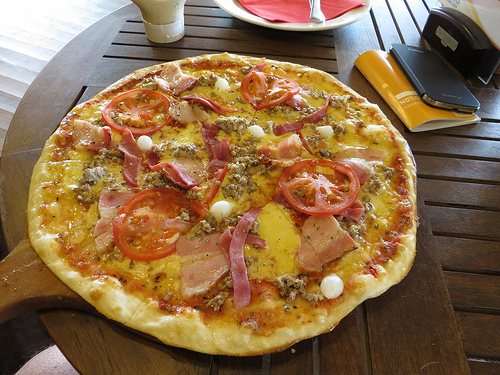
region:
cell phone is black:
[387, 33, 486, 113]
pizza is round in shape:
[21, 47, 423, 361]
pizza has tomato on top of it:
[23, 47, 425, 359]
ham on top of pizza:
[22, 47, 421, 357]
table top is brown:
[1, 0, 498, 371]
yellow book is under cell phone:
[350, 39, 482, 134]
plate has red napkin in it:
[211, 1, 373, 32]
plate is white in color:
[212, 0, 374, 34]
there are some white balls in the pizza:
[23, 47, 423, 359]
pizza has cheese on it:
[20, 47, 421, 361]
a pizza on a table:
[56, 43, 388, 287]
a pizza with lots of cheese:
[24, 54, 467, 356]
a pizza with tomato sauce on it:
[78, 71, 453, 293]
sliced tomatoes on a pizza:
[62, 25, 417, 306]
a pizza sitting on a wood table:
[21, 26, 442, 304]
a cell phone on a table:
[398, 0, 478, 123]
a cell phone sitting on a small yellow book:
[377, 40, 493, 137]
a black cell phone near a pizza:
[370, 16, 496, 129]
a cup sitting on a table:
[118, 6, 218, 71]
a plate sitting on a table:
[196, 0, 443, 39]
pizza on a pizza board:
[7, 215, 109, 340]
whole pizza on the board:
[43, 52, 439, 362]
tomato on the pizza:
[114, 183, 205, 263]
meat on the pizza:
[222, 201, 268, 325]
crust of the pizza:
[138, 287, 234, 359]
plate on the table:
[219, 3, 397, 30]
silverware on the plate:
[299, 4, 344, 27]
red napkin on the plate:
[245, 6, 372, 24]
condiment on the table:
[118, 7, 232, 51]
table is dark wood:
[435, 172, 496, 372]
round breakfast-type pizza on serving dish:
[23, 50, 423, 360]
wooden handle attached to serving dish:
[1, 232, 92, 329]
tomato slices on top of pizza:
[105, 68, 365, 263]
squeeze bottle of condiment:
[129, 0, 193, 47]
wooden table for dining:
[0, 0, 499, 374]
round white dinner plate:
[213, 0, 373, 35]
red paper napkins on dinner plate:
[235, 0, 367, 27]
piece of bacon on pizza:
[68, 118, 115, 155]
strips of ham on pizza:
[217, 198, 261, 310]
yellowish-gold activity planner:
[351, 49, 483, 133]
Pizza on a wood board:
[1, 50, 418, 355]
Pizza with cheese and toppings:
[32, 52, 417, 354]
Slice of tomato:
[278, 156, 360, 217]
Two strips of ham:
[220, 201, 267, 310]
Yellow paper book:
[352, 48, 481, 132]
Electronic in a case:
[390, 41, 481, 116]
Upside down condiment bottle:
[127, 0, 189, 44]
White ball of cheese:
[210, 198, 231, 220]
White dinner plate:
[211, 0, 373, 32]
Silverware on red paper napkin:
[235, 0, 363, 24]